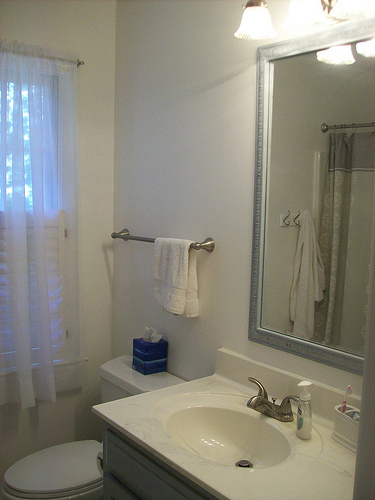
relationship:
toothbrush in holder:
[340, 382, 358, 411] [334, 406, 363, 452]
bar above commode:
[110, 223, 213, 255] [4, 351, 189, 496]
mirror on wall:
[243, 17, 374, 375] [105, 0, 367, 388]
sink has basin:
[93, 347, 358, 500] [166, 403, 295, 474]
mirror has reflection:
[243, 17, 374, 375] [282, 123, 374, 350]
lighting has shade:
[232, 0, 373, 43] [232, 8, 277, 44]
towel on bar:
[149, 236, 200, 319] [110, 223, 213, 255]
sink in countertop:
[93, 347, 358, 500] [92, 347, 356, 499]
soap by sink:
[294, 377, 318, 443] [93, 347, 358, 500]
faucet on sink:
[240, 374, 297, 421] [93, 347, 358, 500]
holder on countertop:
[334, 406, 363, 452] [92, 347, 356, 499]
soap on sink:
[294, 377, 318, 443] [93, 347, 358, 500]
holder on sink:
[334, 406, 363, 452] [93, 347, 358, 500]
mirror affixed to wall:
[243, 17, 374, 375] [105, 0, 367, 388]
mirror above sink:
[243, 17, 374, 375] [93, 347, 358, 500]